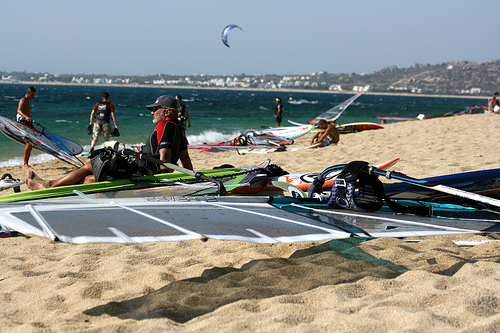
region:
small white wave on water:
[283, 89, 323, 108]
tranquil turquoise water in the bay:
[43, 101, 79, 125]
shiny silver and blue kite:
[210, 14, 252, 57]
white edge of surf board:
[46, 222, 126, 253]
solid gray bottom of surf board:
[179, 206, 228, 235]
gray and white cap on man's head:
[126, 77, 209, 117]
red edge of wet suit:
[123, 116, 202, 155]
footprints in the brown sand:
[143, 259, 310, 309]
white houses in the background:
[251, 63, 360, 90]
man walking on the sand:
[75, 83, 126, 153]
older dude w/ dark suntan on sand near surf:
[20, 92, 196, 198]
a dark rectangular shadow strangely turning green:
[37, 228, 407, 330]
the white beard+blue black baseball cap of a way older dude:
[143, 93, 188, 126]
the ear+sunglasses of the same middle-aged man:
[142, 103, 174, 117]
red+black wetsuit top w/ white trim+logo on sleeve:
[131, 115, 192, 176]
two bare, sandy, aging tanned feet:
[21, 167, 53, 192]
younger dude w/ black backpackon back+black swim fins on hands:
[80, 88, 125, 160]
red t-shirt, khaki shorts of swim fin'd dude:
[90, 98, 115, 140]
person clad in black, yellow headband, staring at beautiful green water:
[271, 93, 284, 128]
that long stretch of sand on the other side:
[0, 78, 499, 92]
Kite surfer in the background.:
[213, 17, 328, 103]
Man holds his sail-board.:
[0, 81, 80, 164]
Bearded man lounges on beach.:
[32, 94, 184, 187]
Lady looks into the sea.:
[268, 94, 286, 126]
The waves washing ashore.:
[185, 126, 243, 144]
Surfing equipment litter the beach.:
[2, 156, 499, 242]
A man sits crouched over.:
[309, 116, 339, 147]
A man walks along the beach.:
[89, 93, 124, 147]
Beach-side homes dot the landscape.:
[3, 68, 499, 91]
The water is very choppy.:
[185, 92, 269, 129]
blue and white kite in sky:
[219, 17, 245, 52]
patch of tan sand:
[351, 286, 489, 325]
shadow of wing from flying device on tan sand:
[68, 236, 390, 329]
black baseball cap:
[140, 89, 180, 111]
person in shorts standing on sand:
[268, 94, 285, 126]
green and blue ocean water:
[206, 93, 253, 119]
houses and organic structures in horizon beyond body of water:
[302, 73, 498, 93]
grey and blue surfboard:
[1, 116, 84, 158]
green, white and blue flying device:
[1, 156, 498, 241]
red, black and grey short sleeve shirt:
[144, 118, 191, 167]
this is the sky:
[256, 12, 368, 69]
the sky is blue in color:
[286, 17, 321, 37]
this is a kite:
[218, 20, 241, 47]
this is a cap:
[147, 95, 176, 107]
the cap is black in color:
[163, 94, 170, 102]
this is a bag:
[95, 104, 111, 116]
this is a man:
[90, 94, 120, 140]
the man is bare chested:
[328, 122, 339, 139]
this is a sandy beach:
[101, 248, 296, 316]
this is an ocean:
[203, 85, 260, 120]